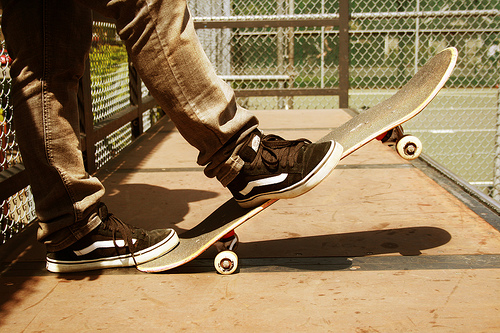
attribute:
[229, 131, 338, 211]
sneaker — white, black, shoe, covering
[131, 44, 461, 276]
skateboard — tipped up, white, gray, black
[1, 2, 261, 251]
jeans — gray, denim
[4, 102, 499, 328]
ramp — brown, wood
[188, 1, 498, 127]
fence — chain link, metal, gray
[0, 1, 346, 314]
man — standing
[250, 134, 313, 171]
laces — brown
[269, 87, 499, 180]
court — green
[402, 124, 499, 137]
line — white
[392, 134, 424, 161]
wheel — white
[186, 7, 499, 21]
post — dark gray, metal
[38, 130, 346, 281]
shoes — black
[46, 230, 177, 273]
soles — white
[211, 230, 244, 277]
wheels — white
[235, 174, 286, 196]
stripe — white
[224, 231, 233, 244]
details — red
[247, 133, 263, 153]
tag — white